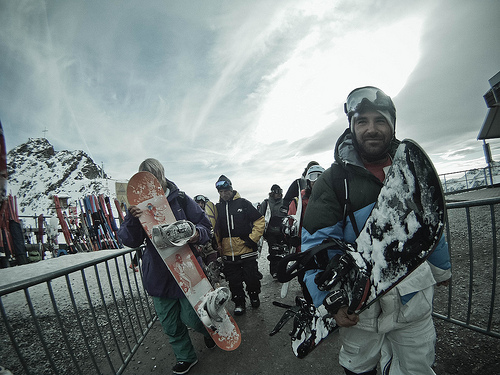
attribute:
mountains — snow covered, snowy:
[12, 129, 123, 236]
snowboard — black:
[291, 138, 447, 355]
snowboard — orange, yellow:
[128, 168, 244, 353]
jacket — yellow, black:
[206, 200, 268, 259]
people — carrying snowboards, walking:
[128, 80, 446, 375]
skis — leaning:
[50, 184, 120, 249]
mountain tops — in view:
[15, 133, 86, 181]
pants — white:
[340, 319, 446, 371]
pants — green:
[147, 287, 213, 361]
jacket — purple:
[171, 191, 212, 237]